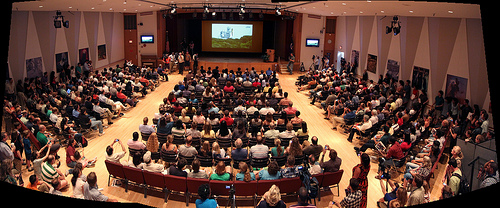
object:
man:
[101, 137, 130, 164]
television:
[210, 24, 255, 53]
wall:
[202, 21, 262, 54]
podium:
[268, 48, 275, 62]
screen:
[197, 17, 266, 57]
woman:
[64, 138, 82, 164]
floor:
[110, 121, 130, 138]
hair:
[145, 132, 160, 152]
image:
[211, 23, 257, 50]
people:
[182, 51, 195, 62]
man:
[445, 158, 463, 200]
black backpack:
[449, 173, 472, 197]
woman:
[232, 160, 259, 182]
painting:
[349, 47, 359, 68]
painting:
[381, 57, 401, 85]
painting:
[363, 51, 377, 74]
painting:
[413, 64, 431, 95]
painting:
[441, 72, 469, 102]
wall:
[333, 12, 494, 113]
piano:
[139, 54, 161, 67]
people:
[217, 120, 233, 139]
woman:
[195, 186, 219, 208]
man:
[39, 153, 68, 191]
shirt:
[39, 161, 59, 186]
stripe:
[43, 162, 58, 177]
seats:
[105, 160, 126, 187]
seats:
[117, 162, 147, 194]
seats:
[141, 170, 173, 200]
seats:
[164, 174, 193, 203]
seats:
[186, 178, 212, 203]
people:
[105, 137, 129, 164]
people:
[127, 154, 145, 169]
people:
[136, 151, 165, 174]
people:
[169, 158, 187, 178]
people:
[187, 160, 207, 180]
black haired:
[404, 130, 412, 143]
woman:
[403, 133, 413, 150]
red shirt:
[401, 141, 413, 151]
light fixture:
[272, 6, 293, 20]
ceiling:
[9, 1, 478, 20]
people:
[209, 160, 233, 181]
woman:
[348, 153, 372, 207]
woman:
[201, 123, 219, 137]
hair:
[218, 121, 231, 137]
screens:
[139, 33, 155, 44]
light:
[384, 15, 406, 38]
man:
[332, 177, 366, 208]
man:
[318, 146, 348, 171]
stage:
[171, 48, 298, 74]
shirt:
[337, 190, 364, 207]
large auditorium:
[2, 0, 482, 205]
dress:
[349, 164, 369, 208]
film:
[212, 23, 258, 49]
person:
[284, 53, 297, 73]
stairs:
[281, 65, 295, 73]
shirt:
[213, 173, 237, 181]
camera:
[112, 138, 120, 145]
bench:
[142, 61, 153, 64]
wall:
[123, 10, 332, 66]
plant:
[276, 50, 284, 58]